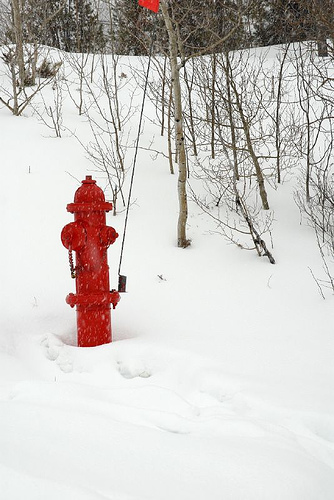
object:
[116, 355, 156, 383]
prints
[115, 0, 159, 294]
red flag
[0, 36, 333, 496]
snow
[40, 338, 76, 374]
footprints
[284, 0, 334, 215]
trees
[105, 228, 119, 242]
cap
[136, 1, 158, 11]
flag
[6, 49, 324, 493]
field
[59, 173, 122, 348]
fire hydrant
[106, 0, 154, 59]
pine trees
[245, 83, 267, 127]
branch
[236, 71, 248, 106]
branch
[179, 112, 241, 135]
branch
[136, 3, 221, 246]
birch tree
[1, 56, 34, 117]
birch tree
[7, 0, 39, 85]
birch tree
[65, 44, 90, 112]
birch tree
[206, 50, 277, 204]
birch tree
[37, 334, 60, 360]
footprint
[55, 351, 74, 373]
footprint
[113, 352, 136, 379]
footprint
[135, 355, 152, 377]
footprint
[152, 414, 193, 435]
footprint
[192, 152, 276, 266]
branch snow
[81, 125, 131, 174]
branch snow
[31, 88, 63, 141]
branch snow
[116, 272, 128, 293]
spring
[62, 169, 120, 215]
cap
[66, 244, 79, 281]
chain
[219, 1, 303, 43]
sky